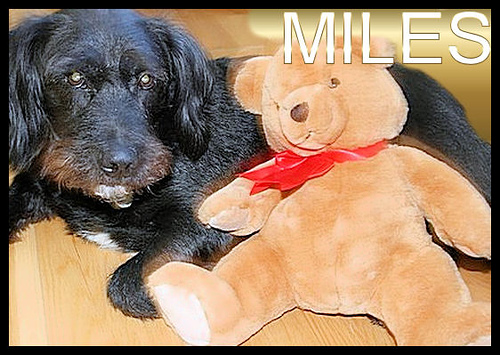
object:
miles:
[275, 11, 493, 69]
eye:
[133, 73, 153, 93]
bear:
[137, 36, 499, 347]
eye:
[326, 78, 344, 92]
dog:
[5, 10, 494, 321]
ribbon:
[234, 136, 400, 198]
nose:
[287, 101, 313, 126]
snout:
[285, 101, 338, 148]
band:
[233, 136, 391, 198]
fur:
[291, 227, 361, 265]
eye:
[268, 95, 285, 114]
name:
[276, 10, 490, 68]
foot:
[144, 260, 247, 354]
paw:
[194, 181, 276, 239]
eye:
[60, 70, 88, 89]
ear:
[142, 15, 219, 163]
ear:
[8, 10, 62, 175]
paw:
[104, 263, 165, 321]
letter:
[282, 10, 337, 65]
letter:
[342, 11, 354, 65]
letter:
[359, 12, 394, 64]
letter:
[400, 10, 443, 65]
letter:
[448, 10, 494, 66]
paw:
[426, 209, 498, 262]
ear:
[232, 55, 272, 116]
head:
[3, 9, 219, 208]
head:
[234, 36, 411, 160]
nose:
[105, 142, 141, 169]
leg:
[214, 232, 294, 343]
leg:
[109, 214, 244, 322]